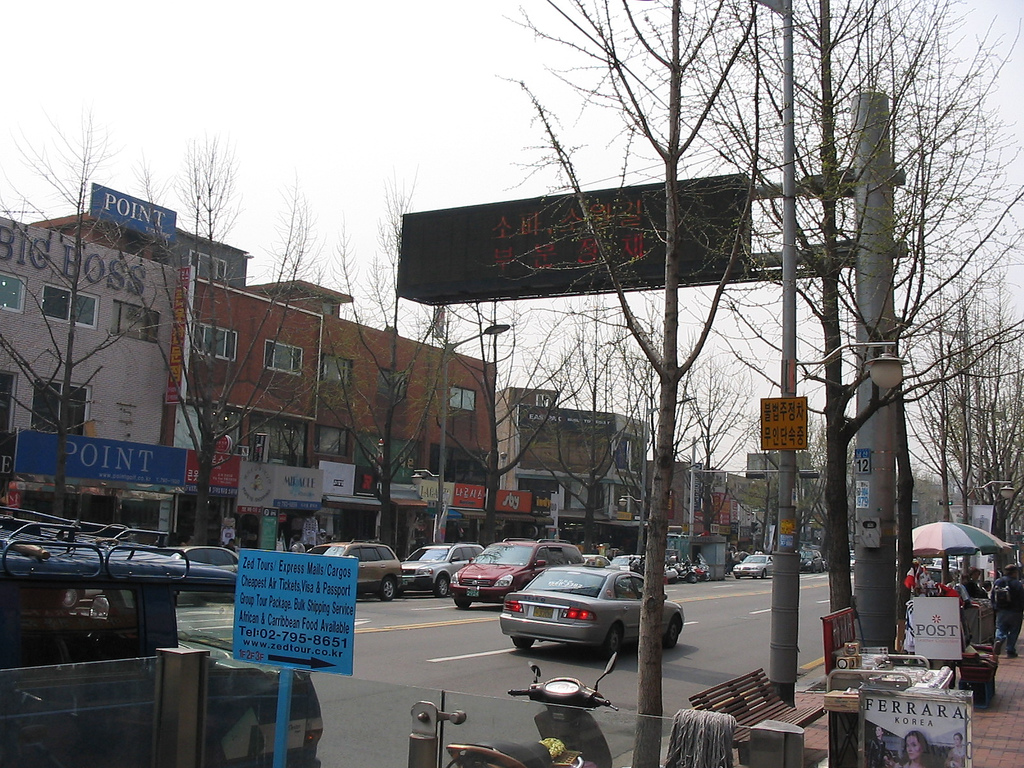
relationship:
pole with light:
[752, 399, 835, 763] [752, 49, 804, 762]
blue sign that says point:
[0, 413, 206, 502] [62, 435, 162, 475]